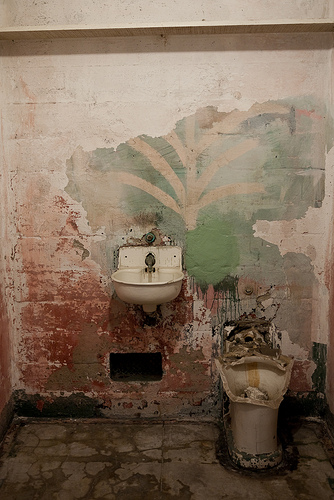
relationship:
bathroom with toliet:
[0, 41, 332, 499] [205, 315, 295, 471]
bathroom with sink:
[0, 41, 332, 499] [108, 223, 195, 318]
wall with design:
[9, 60, 330, 421] [39, 101, 327, 372]